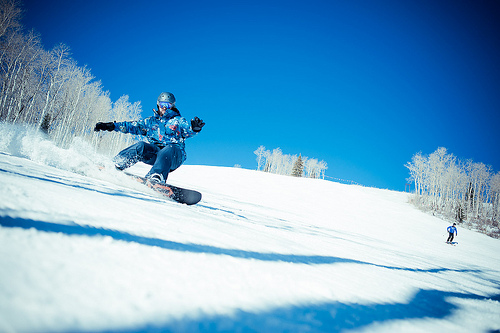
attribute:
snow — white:
[1, 121, 499, 331]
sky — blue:
[0, 0, 500, 205]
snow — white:
[275, 185, 390, 325]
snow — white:
[284, 244, 393, 309]